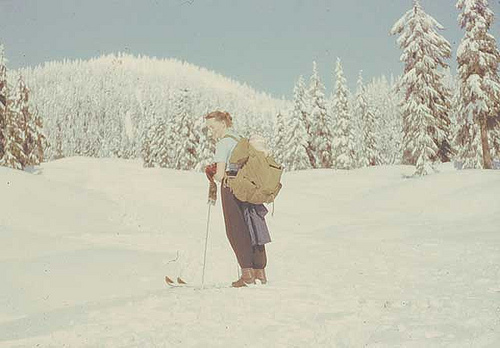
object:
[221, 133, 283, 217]
backpack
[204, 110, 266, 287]
person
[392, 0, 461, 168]
tree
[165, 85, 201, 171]
trees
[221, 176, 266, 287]
pants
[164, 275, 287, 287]
skii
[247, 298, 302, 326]
snow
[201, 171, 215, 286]
ski pole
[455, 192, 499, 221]
snow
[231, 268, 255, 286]
boot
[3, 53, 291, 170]
mountain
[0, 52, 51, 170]
trees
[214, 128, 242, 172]
shirt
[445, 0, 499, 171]
tree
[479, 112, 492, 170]
trunk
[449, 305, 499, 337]
snow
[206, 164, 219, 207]
scarf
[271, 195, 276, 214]
strap